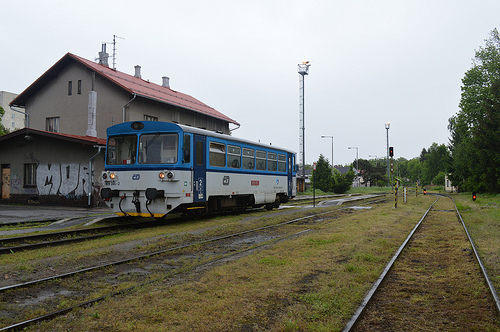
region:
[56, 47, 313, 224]
one passenger train car at station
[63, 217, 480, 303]
train tracks in the foreground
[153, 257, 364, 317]
patchy green grass between the tracks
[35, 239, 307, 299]
section of track looks wet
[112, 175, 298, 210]
bottom half of car is white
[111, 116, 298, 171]
top half of car is blue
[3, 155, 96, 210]
graffiti is painted on the building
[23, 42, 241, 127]
small building has red roof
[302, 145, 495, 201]
green trees in the background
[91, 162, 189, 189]
two headlights on the train are on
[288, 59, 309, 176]
A tower stands tall.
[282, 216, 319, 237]
The tracks are covered in grass.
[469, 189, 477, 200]
The signal is red.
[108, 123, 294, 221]
The train is white and blue.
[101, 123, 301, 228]
The train is sitting on the tracks.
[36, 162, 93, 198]
the wall is graffitied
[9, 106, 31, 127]
The water drain is white.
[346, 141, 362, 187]
The street lamp is off.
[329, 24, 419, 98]
The sky is overcast.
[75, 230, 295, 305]
The ground is wet.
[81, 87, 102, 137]
Long skinny white chimney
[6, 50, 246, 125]
Red triangle shaped rooftop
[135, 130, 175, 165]
Clear rectangle shaped window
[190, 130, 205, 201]
Long blue train door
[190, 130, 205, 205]
Rectangle blue train door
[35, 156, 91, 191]
Large white wall graffiti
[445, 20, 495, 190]
Big bushy green tree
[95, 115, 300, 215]
Long multi-colored stationary train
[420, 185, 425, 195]
Rectangle shaped traffic light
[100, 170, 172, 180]
Round set of headlights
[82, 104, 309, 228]
a blue and white train car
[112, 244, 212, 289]
some patches of mud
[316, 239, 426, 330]
train track in the grass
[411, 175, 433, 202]
a red traffic light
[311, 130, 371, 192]
a few street lights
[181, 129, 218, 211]
a dark blue door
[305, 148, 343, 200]
a full evergreen tree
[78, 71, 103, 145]
a tall chimney stack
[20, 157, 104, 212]
a large piece of graffiti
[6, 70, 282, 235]
a two story building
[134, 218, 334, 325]
the grass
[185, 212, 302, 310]
the grass